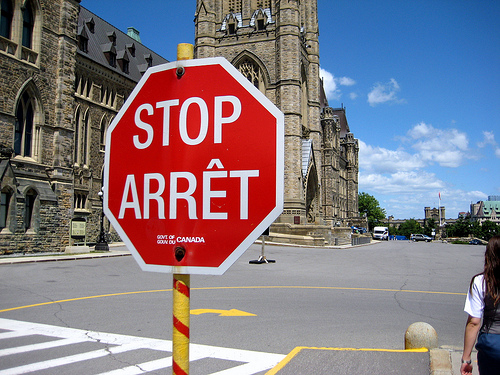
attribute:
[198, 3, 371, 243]
building — large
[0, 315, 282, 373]
paint — white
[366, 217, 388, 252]
car — grey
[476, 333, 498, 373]
pants — blue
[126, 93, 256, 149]
stop — french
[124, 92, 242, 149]
word stop — english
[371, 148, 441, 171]
clouds — white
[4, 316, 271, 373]
stripes — white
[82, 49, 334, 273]
sign — 8-sided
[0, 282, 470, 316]
line — yellow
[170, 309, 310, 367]
arrow — yellow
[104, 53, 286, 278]
stop sign — red, white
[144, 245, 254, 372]
pole — yellow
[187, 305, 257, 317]
arrow — yellow, directional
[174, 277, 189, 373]
striped pole — red, yellow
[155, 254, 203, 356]
pole — yellow, red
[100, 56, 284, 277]
sign — red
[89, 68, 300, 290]
stop sign — bilingual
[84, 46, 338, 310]
sign — red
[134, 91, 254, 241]
lettering — white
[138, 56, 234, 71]
border — white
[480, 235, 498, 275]
hair — brown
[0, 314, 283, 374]
lines — white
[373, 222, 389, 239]
bus — white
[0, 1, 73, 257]
building — gothic